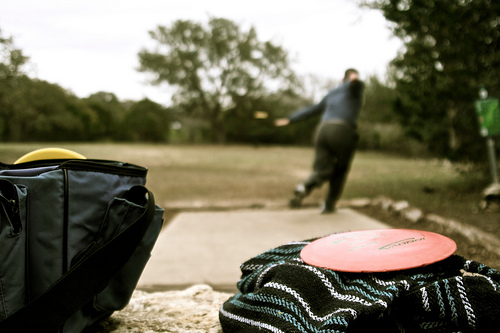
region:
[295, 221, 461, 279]
a red frisbee with lettering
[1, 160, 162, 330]
a black bag with pockets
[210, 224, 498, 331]
a striped pullover with a frisbee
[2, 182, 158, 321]
the strap of the bag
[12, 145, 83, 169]
a yellow frisbee in the bag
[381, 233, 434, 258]
black lettering on the red frisbee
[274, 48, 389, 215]
a man throwing a frisbee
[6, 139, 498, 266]
a field for throwing frisbees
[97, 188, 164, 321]
front pocket of the black bag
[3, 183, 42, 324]
back pocket of the bag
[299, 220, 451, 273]
an orange frisbee on a shirt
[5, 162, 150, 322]
a grey bag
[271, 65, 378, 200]
a person running in a field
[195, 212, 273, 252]
a tan cement slab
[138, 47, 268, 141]
a faded tree in the background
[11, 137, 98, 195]
a yellow frisbee in a bag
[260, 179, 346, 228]
a persons two feet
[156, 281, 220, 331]
a tan rock on the ground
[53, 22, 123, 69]
faded grey sky in background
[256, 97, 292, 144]
a persons left hand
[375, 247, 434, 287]
part of a dish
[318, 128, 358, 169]
part of a trouser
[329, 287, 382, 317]
part of a sweater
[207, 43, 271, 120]
part of a tree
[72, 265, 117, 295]
handle of a bag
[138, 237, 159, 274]
part of a pocket of a bag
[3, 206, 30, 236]
part of a zip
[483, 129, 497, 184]
part of a post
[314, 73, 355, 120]
part of a top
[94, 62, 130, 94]
part of some clouds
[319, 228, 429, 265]
a re disk lying on a shirt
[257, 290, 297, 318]
blue stripes on a hoodie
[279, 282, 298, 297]
a white stripe on a black hoodie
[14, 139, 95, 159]
the edge of a yellow circle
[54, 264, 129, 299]
a black strap on a bag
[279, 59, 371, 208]
a person tossing a yellow object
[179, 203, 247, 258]
a cement slab on the ground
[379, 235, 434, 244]
black writing on a red disk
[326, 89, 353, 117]
a blue shirt covering a torso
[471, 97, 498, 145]
a green sign nearby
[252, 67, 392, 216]
man playing game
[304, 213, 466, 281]
disk shaped sporting equipment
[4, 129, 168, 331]
dark grey bag with black handle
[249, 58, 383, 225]
man throwing disk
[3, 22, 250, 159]
trees and cloudy sky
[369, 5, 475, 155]
trees and cloudy sky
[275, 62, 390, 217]
man with blue shirt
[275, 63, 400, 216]
man with brown pants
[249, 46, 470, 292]
man practicing how to throw disk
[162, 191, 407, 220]
white boundary line